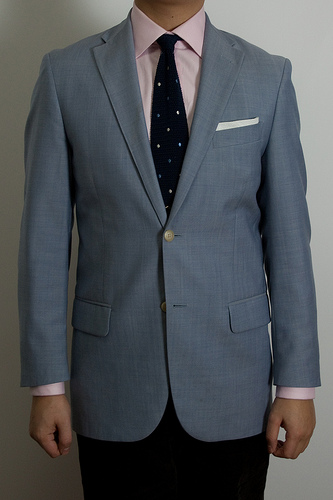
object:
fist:
[28, 391, 74, 460]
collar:
[130, 0, 206, 59]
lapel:
[91, 18, 170, 238]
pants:
[77, 393, 273, 500]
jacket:
[16, 3, 322, 444]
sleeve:
[28, 382, 66, 397]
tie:
[150, 30, 190, 217]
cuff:
[270, 380, 322, 392]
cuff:
[20, 375, 71, 391]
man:
[17, 0, 322, 500]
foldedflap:
[227, 290, 272, 333]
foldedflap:
[71, 295, 112, 338]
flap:
[226, 291, 272, 335]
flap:
[71, 296, 112, 338]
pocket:
[226, 289, 273, 371]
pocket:
[70, 294, 113, 367]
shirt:
[129, 1, 207, 143]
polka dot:
[157, 81, 161, 87]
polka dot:
[157, 113, 161, 117]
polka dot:
[176, 110, 180, 115]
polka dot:
[166, 127, 170, 132]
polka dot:
[156, 143, 160, 149]